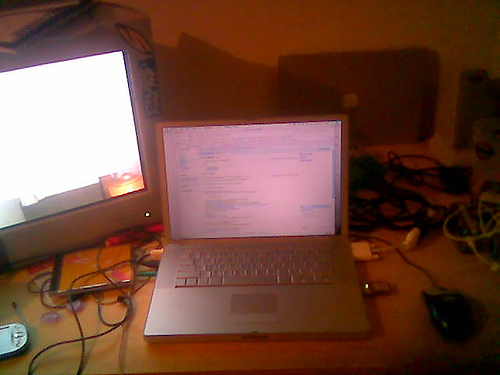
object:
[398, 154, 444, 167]
wires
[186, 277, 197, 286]
key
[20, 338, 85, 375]
black wire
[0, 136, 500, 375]
table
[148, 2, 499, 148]
wall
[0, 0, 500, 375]
building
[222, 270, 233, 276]
key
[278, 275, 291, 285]
button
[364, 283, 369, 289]
light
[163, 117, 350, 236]
screen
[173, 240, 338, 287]
keyboard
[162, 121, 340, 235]
print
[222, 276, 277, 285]
key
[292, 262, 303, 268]
key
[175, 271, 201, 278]
key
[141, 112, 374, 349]
laptop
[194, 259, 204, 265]
key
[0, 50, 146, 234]
screen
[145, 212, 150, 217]
light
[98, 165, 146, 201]
picture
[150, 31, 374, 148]
shadow